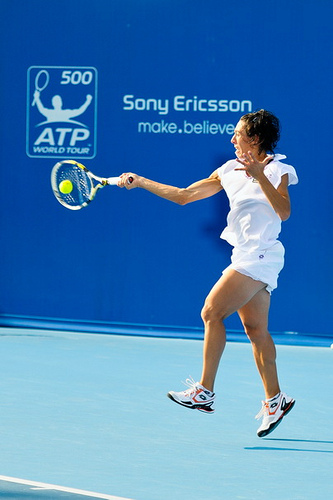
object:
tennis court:
[0, 324, 333, 500]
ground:
[0, 0, 333, 500]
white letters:
[25, 64, 252, 159]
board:
[0, 1, 332, 347]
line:
[0, 474, 124, 500]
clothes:
[217, 152, 298, 296]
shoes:
[167, 375, 296, 438]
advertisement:
[25, 65, 252, 160]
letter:
[157, 99, 168, 115]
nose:
[231, 134, 237, 144]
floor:
[145, 78, 231, 109]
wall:
[0, 0, 333, 346]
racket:
[50, 159, 133, 211]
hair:
[240, 108, 281, 158]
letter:
[174, 95, 186, 112]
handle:
[107, 177, 121, 186]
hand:
[117, 173, 138, 190]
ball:
[59, 179, 73, 194]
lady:
[116, 108, 296, 437]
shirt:
[218, 153, 299, 253]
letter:
[123, 94, 135, 111]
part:
[2, 472, 121, 495]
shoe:
[166, 375, 216, 414]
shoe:
[254, 391, 296, 438]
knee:
[201, 303, 219, 325]